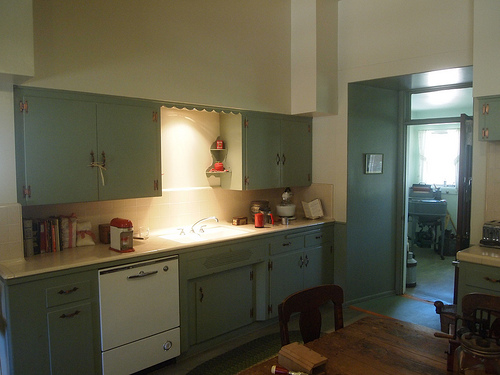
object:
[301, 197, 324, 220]
book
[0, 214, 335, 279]
counter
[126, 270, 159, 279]
handle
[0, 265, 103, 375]
cabinet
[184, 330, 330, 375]
rug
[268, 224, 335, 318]
kitchen cabinet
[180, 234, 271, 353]
cabinet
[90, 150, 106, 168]
handle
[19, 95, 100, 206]
cabinet door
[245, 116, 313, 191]
door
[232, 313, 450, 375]
table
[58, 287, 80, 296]
handle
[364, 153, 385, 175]
photo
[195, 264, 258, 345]
cabinet door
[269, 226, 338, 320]
drawer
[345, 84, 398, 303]
wall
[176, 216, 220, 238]
water faucet.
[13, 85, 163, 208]
cabinet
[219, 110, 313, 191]
cabinet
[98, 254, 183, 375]
cabinet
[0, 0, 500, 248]
white wall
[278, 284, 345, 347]
chair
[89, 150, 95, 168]
handle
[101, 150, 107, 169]
handle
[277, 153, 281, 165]
handle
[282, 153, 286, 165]
handle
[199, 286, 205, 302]
handle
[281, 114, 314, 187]
door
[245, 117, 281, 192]
door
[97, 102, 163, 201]
door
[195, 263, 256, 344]
door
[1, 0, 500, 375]
wall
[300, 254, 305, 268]
handle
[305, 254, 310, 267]
handle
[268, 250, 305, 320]
door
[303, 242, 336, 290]
door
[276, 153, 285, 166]
handle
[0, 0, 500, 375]
kitchen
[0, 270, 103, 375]
drawer